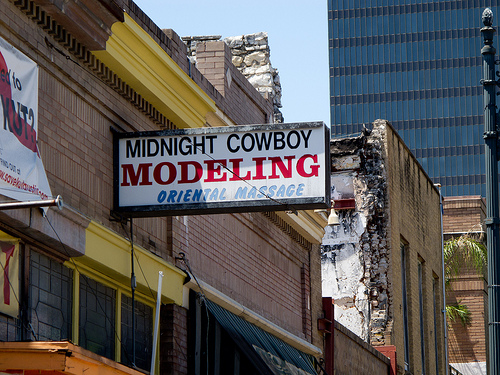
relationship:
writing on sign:
[150, 180, 305, 209] [125, 113, 328, 229]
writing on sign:
[147, 180, 308, 216] [77, 87, 347, 242]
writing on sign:
[122, 156, 377, 191] [92, 92, 362, 196]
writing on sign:
[120, 125, 321, 160] [123, 115, 351, 221]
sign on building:
[120, 121, 333, 220] [16, 77, 376, 366]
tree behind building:
[438, 231, 487, 271] [318, 207, 495, 360]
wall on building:
[321, 155, 408, 367] [296, 148, 436, 330]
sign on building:
[103, 125, 309, 235] [30, 43, 359, 303]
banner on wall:
[0, 70, 76, 218] [6, 54, 315, 315]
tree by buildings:
[438, 231, 487, 271] [220, 88, 460, 355]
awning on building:
[206, 292, 348, 362] [44, 109, 391, 370]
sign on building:
[120, 121, 333, 220] [21, 71, 341, 351]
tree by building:
[438, 231, 498, 297] [345, 62, 481, 324]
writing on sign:
[111, 114, 299, 174] [100, 111, 312, 204]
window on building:
[329, 69, 352, 100] [329, 43, 479, 248]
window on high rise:
[360, 74, 378, 97] [334, 1, 488, 200]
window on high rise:
[390, 75, 400, 95] [334, 1, 488, 200]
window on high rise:
[410, 63, 428, 90] [334, 1, 488, 200]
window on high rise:
[439, 64, 459, 93] [334, 1, 488, 200]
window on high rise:
[468, 88, 480, 117] [334, 1, 488, 200]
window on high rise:
[442, 94, 462, 117] [334, 1, 488, 200]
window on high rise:
[428, 92, 446, 117] [334, 1, 488, 200]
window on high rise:
[420, 95, 436, 122] [334, 1, 488, 200]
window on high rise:
[433, 150, 453, 179] [334, 1, 488, 200]